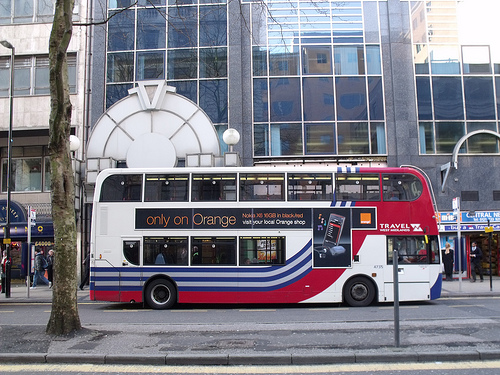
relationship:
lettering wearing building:
[464, 208, 498, 221] [85, 0, 495, 287]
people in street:
[1, 247, 54, 289] [2, 163, 492, 372]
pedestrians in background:
[433, 226, 493, 279] [2, 196, 94, 298]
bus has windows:
[89, 166, 444, 305] [100, 174, 424, 204]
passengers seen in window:
[147, 240, 222, 267] [145, 236, 187, 268]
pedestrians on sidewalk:
[442, 241, 485, 282] [440, 277, 498, 295]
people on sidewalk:
[0, 248, 54, 291] [440, 277, 498, 295]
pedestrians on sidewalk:
[442, 241, 485, 282] [9, 285, 89, 305]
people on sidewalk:
[0, 248, 54, 291] [9, 285, 89, 305]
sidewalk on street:
[0, 276, 499, 303] [10, 93, 495, 369]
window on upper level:
[143, 171, 190, 202] [92, 166, 434, 211]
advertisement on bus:
[135, 207, 329, 232] [82, 161, 447, 315]